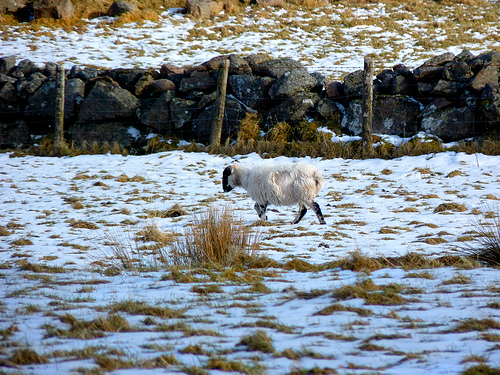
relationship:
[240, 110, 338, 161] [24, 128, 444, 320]
bush in field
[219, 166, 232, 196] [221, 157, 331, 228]
face of sheep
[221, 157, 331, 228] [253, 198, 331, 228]
sheep has legs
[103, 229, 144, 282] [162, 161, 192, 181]
grass poking out of snow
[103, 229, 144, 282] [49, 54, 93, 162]
grass near fence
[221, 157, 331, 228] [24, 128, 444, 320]
sheep in field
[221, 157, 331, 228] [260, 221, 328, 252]
sheep on ground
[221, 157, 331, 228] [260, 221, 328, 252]
sheep walking on ground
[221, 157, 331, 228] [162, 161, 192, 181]
sheep in snow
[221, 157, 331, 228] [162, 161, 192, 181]
sheep walking in snow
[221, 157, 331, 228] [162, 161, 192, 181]
sheep on snow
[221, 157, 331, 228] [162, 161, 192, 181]
sheep walking on snow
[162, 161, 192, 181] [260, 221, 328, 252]
snow covering ground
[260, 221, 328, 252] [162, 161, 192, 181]
ground with snow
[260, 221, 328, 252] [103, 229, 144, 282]
ground with grass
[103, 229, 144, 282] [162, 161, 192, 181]
grass and snow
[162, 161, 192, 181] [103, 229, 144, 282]
snow and grass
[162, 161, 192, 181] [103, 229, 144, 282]
snow on top of grass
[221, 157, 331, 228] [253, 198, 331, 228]
animal has legs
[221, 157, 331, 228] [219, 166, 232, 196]
animal has face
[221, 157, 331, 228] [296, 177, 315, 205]
sheep has fur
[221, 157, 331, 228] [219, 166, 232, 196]
sheep has face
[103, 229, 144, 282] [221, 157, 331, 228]
grass near sheep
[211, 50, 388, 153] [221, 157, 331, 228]
stakes behind sheep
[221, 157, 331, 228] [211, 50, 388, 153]
sheep near stakes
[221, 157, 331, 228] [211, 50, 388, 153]
sheep walking near stakes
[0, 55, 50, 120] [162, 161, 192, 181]
rocks and snow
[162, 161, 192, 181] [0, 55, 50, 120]
snow and rocks